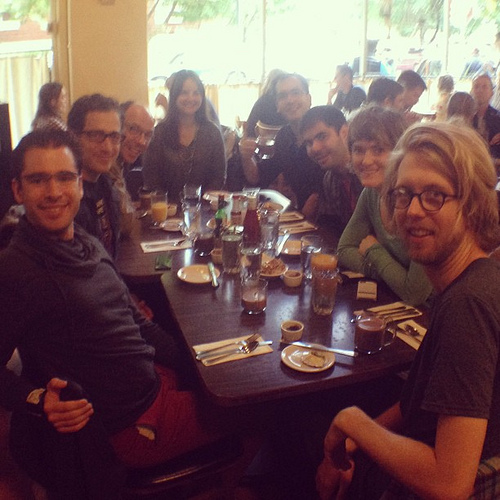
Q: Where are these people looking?
A: At camera.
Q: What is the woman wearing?
A: Dark shirt.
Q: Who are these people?
A: Friends.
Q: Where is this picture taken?
A: AT the restaurant.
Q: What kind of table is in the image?
A: Dark brown wooden table.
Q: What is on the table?
A: Drinks, plates, forks, knives, glasses.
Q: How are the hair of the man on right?
A: Long blonde.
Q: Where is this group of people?
A: Restaurant.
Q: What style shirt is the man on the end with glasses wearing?
A: A t-shirt.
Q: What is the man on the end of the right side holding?
A: A drink.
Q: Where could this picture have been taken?
A: Restaurant.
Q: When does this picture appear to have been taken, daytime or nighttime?
A: Daytime.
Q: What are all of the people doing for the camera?
A: Smiling.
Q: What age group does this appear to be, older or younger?
A: Younger.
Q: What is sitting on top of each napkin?
A: Utensils.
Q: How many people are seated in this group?
A: Eight.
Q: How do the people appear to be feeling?
A: Happy.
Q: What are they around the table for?
A: Food and drink.